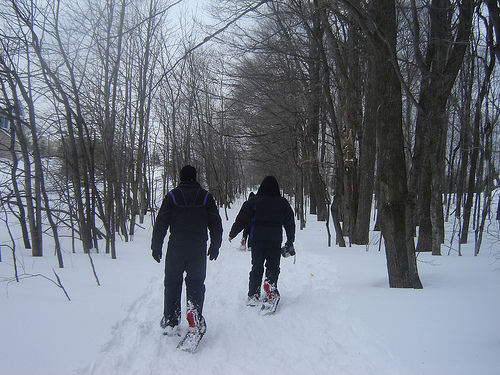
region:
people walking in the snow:
[153, 168, 308, 363]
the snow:
[337, 298, 425, 355]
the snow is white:
[32, 316, 109, 362]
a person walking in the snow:
[250, 177, 298, 284]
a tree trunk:
[377, 189, 426, 287]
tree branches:
[187, 58, 238, 101]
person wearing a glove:
[205, 250, 219, 259]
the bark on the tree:
[415, 165, 450, 253]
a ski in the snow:
[176, 330, 207, 350]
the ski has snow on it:
[253, 298, 281, 314]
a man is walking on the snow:
[155, 163, 222, 339]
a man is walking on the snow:
[226, 171, 295, 313]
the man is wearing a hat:
[177, 165, 198, 180]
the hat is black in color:
[175, 165, 197, 181]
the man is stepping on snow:
[155, 313, 212, 338]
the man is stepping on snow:
[245, 285, 280, 313]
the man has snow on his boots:
[159, 311, 216, 347]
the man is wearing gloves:
[147, 242, 222, 268]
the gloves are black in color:
[152, 245, 221, 262]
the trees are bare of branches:
[6, 0, 496, 300]